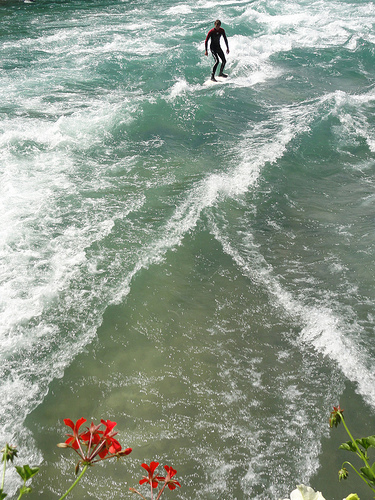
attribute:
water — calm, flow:
[2, 2, 373, 498]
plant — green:
[324, 403, 373, 498]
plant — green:
[127, 458, 183, 498]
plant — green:
[47, 413, 132, 498]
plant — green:
[12, 463, 38, 499]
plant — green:
[0, 441, 19, 498]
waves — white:
[0, 1, 374, 498]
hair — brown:
[211, 16, 220, 29]